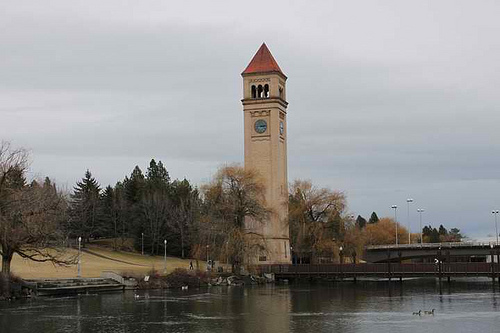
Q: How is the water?
A: It is very calm.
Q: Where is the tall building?
A: In the park.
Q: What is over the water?
A: A walking bridge.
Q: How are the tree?
A: Tall with green leaves.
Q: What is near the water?
A: A tall tower.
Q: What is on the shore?
A: A line of trees.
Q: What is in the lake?
A: Water.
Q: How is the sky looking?
A: With white clouds.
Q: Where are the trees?
A: Beside the water.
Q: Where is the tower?
A: By the water.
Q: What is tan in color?
A: The tower.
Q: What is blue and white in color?
A: The sky.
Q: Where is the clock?
A: In the tower.